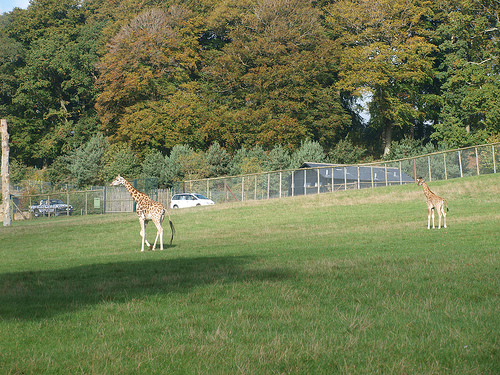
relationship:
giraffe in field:
[112, 175, 175, 252] [1, 171, 499, 374]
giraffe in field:
[415, 178, 452, 231] [1, 171, 499, 374]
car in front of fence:
[171, 194, 212, 211] [9, 141, 498, 225]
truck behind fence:
[31, 200, 73, 218] [9, 141, 498, 225]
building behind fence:
[286, 163, 420, 201] [9, 141, 498, 225]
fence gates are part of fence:
[104, 182, 173, 215] [9, 141, 498, 225]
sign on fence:
[92, 197, 102, 209] [9, 141, 498, 225]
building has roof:
[286, 163, 420, 201] [309, 159, 416, 184]